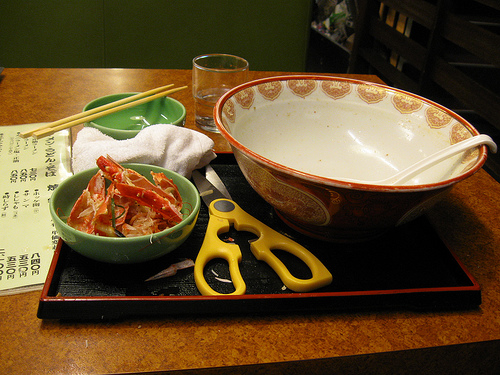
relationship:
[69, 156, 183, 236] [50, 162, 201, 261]
crab met in bowl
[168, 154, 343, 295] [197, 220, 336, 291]
scissors in handles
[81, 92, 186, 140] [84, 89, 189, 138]
bowl laying on top of bowl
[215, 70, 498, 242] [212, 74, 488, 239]
bowl has bowl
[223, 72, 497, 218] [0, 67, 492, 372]
bowl on tabletop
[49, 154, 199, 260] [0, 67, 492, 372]
bowl on tabletop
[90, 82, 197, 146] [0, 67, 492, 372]
bowl on tabletop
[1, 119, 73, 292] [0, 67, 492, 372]
menu on tabletop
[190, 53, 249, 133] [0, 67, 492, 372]
cup on tabletop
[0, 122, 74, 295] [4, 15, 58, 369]
menu on left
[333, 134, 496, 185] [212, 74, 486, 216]
spoon in bowl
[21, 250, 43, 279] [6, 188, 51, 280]
black writing on menu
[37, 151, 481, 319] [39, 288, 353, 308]
plate has edge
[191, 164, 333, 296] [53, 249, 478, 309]
scissors on plate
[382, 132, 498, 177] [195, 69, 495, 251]
spoon on bowl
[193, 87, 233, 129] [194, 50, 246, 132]
water in cup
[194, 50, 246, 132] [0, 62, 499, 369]
cup on table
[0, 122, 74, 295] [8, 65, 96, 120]
menu on table